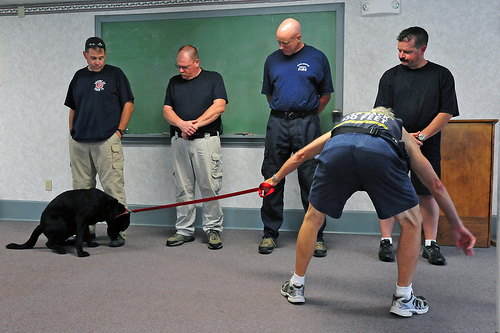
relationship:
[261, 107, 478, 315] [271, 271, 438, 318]
man wears shoes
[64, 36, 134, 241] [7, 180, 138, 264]
man watch dog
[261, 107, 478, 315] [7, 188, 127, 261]
man train dog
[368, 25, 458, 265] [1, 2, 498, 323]
man in room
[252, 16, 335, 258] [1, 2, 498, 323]
man in room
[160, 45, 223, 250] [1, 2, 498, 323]
man in room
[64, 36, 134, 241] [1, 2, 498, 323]
man in room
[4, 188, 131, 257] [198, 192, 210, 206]
dog pulling leash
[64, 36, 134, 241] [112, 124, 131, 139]
man has watch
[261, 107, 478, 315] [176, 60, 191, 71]
man wears glasses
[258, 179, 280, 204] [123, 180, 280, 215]
hand holding leash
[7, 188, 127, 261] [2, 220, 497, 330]
dog sitting on carpet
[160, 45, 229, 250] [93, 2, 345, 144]
man standing against chalk board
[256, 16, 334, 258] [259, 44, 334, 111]
man wearing tee shirt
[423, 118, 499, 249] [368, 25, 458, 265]
podium behind man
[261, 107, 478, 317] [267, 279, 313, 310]
man wearing shoe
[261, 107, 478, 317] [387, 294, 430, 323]
man wearing shoe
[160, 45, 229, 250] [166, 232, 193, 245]
man wearing shoe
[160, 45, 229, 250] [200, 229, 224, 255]
man wearing shoe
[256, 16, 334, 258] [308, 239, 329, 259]
man wearing shoe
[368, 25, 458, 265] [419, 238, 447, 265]
man wearing shoe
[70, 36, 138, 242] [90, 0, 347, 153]
man standing by chalkboard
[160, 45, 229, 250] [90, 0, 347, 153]
man standing by chalkboard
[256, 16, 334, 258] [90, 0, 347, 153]
man standing by chalkboard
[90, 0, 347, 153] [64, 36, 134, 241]
chalkboard behind man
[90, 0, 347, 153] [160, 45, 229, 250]
chalkboard behind man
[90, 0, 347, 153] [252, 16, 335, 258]
chalkboard behind man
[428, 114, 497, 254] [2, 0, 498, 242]
podium beside wall